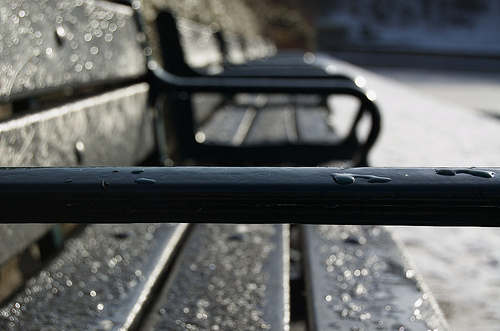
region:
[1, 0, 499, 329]
empty benches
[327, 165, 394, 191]
water on the armrest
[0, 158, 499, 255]
armrest of the chair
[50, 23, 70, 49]
a nail on the chair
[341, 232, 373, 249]
head of the nail on the bench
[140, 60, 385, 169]
armrest of the bench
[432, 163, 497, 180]
water on the armrest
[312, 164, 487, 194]
the drops are clear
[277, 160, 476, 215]
drops of water on armrest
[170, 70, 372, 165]
the arm rest is black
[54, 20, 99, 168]
the screws are dark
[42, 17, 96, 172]
screws in the seat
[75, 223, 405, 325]
the chair bench is wet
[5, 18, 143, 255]
the chair back is wet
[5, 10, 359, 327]
the benches are dark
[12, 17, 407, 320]
the benches are lined up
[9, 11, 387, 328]
the benches are wet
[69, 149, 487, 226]
Black armrest on a bench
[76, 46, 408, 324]
Gray bench with black rails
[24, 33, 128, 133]
Water on a bench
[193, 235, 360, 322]
Rain on a bench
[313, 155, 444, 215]
Rain on a black arm rest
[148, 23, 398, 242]
Benches ina row next to eachother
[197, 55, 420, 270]
Benches for people to sit on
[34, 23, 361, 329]
Rain covered benches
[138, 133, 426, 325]
Soaked bench which is empty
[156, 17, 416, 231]
Row of empty benches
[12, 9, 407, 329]
raindrops on the bench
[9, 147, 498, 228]
arm rest in the foreground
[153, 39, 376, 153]
arm rests in the background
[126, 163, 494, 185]
rain drops on arm rest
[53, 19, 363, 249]
bolts in the bench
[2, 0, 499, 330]
bench with black arm rests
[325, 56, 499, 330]
sidewalk in front of benches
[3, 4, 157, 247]
back of the bench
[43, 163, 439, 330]
seat of the bench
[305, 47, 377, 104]
sunlight on the arm rests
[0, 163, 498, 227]
A black bar in focus going across.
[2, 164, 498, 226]
Most in focus black bar with water on it.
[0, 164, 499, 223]
Black bar with water on it.